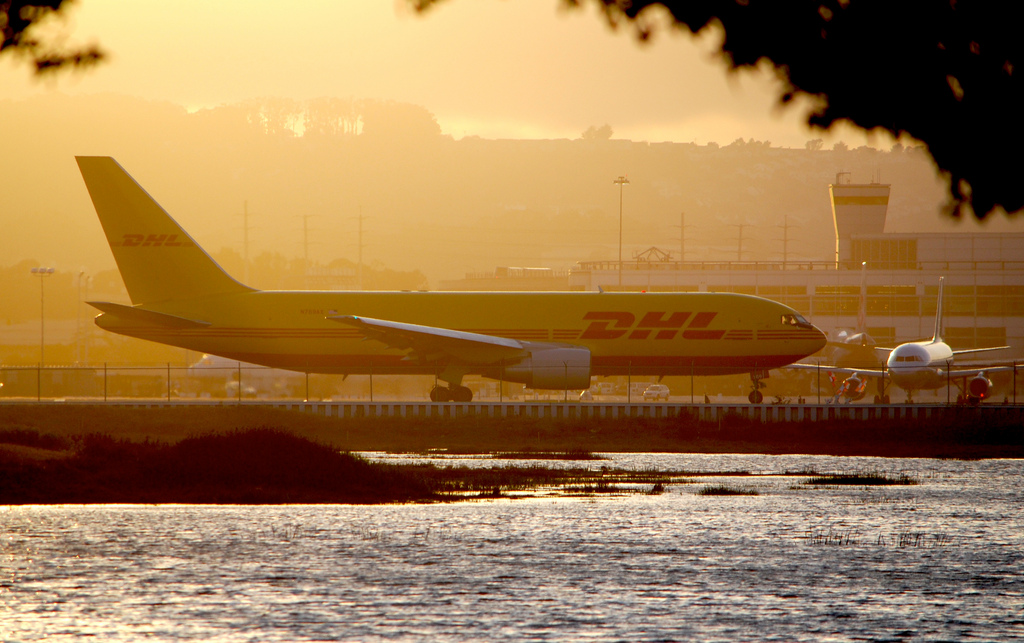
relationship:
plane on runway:
[70, 146, 830, 410] [2, 391, 1024, 415]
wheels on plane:
[425, 379, 478, 404] [70, 146, 830, 410]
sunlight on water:
[21, 486, 1024, 545] [3, 439, 1024, 639]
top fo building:
[594, 252, 1022, 281] [597, 248, 1024, 383]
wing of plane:
[330, 308, 527, 366] [70, 146, 830, 410]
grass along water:
[2, 420, 924, 503] [3, 439, 1024, 639]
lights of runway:
[28, 259, 56, 281] [2, 391, 1024, 415]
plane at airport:
[70, 146, 830, 410] [2, 172, 1024, 444]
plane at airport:
[787, 263, 1024, 409] [2, 172, 1024, 444]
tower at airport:
[821, 170, 899, 269] [2, 172, 1024, 444]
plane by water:
[70, 146, 830, 410] [3, 439, 1024, 639]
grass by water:
[2, 420, 924, 503] [3, 439, 1024, 639]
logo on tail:
[115, 223, 193, 252] [67, 151, 265, 307]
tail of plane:
[67, 151, 265, 307] [70, 146, 830, 410]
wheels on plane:
[745, 385, 766, 407] [70, 146, 830, 410]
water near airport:
[3, 439, 1024, 639] [2, 172, 1024, 444]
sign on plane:
[573, 306, 727, 350] [70, 146, 830, 410]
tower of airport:
[821, 170, 899, 269] [2, 172, 1024, 444]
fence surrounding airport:
[8, 355, 1024, 418] [2, 172, 1024, 444]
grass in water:
[2, 420, 924, 503] [3, 439, 1024, 639]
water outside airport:
[3, 439, 1024, 639] [2, 172, 1024, 444]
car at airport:
[639, 378, 674, 406] [2, 172, 1024, 444]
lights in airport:
[28, 259, 56, 281] [2, 172, 1024, 444]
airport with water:
[2, 172, 1024, 444] [3, 439, 1024, 639]